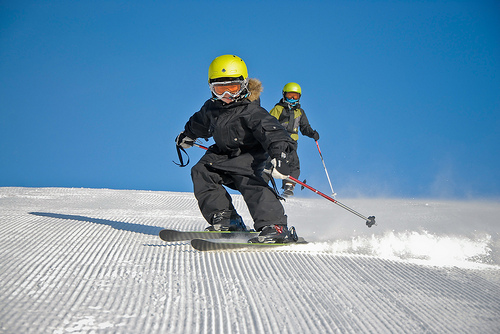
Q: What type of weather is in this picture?
A: It is clear.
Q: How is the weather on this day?
A: It is clear.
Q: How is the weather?
A: It is clear.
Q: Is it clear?
A: Yes, it is clear.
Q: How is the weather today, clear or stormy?
A: It is clear.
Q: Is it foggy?
A: No, it is clear.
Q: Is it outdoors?
A: Yes, it is outdoors.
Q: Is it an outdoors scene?
A: Yes, it is outdoors.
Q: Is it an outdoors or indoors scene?
A: It is outdoors.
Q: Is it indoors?
A: No, it is outdoors.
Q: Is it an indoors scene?
A: No, it is outdoors.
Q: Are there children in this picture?
A: Yes, there is a child.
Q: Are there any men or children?
A: Yes, there is a child.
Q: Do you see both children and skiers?
A: Yes, there are both a child and a skier.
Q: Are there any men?
A: No, there are no men.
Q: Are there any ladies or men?
A: No, there are no men or ladies.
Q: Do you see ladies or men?
A: No, there are no men or ladies.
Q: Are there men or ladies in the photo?
A: No, there are no men or ladies.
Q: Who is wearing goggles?
A: The kid is wearing goggles.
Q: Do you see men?
A: No, there are no men.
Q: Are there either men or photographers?
A: No, there are no men or photographers.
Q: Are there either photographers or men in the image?
A: No, there are no men or photographers.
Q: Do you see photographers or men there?
A: No, there are no men or photographers.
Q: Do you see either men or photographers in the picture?
A: No, there are no men or photographers.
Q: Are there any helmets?
A: Yes, there is a helmet.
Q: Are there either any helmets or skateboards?
A: Yes, there is a helmet.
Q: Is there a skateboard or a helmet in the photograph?
A: Yes, there is a helmet.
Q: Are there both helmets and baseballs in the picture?
A: No, there is a helmet but no baseballs.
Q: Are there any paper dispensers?
A: No, there are no paper dispensers.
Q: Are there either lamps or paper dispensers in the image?
A: No, there are no paper dispensers or lamps.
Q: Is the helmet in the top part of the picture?
A: Yes, the helmet is in the top of the image.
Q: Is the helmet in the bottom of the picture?
A: No, the helmet is in the top of the image.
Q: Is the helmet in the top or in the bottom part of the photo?
A: The helmet is in the top of the image.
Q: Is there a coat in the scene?
A: Yes, there is a coat.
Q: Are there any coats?
A: Yes, there is a coat.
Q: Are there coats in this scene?
A: Yes, there is a coat.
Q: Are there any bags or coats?
A: Yes, there is a coat.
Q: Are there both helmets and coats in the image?
A: Yes, there are both a coat and a helmet.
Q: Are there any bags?
A: No, there are no bags.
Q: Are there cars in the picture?
A: No, there are no cars.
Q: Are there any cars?
A: No, there are no cars.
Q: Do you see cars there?
A: No, there are no cars.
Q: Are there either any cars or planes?
A: No, there are no cars or planes.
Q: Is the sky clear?
A: Yes, the sky is clear.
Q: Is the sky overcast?
A: No, the sky is clear.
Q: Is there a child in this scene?
A: Yes, there is a child.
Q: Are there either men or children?
A: Yes, there is a child.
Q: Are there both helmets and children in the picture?
A: Yes, there are both a child and a helmet.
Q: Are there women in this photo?
A: No, there are no women.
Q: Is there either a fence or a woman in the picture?
A: No, there are no women or fences.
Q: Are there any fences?
A: No, there are no fences.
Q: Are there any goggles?
A: Yes, there are goggles.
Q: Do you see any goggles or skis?
A: Yes, there are goggles.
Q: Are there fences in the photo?
A: No, there are no fences.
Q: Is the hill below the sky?
A: Yes, the hill is below the sky.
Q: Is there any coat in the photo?
A: Yes, there is a coat.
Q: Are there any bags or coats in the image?
A: Yes, there is a coat.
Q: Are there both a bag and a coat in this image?
A: No, there is a coat but no bags.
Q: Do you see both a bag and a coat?
A: No, there is a coat but no bags.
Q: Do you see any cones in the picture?
A: No, there are no cones.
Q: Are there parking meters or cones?
A: No, there are no cones or parking meters.